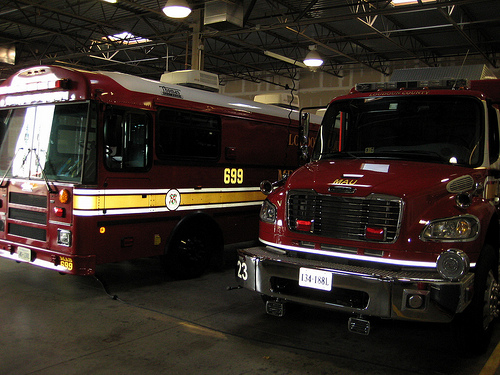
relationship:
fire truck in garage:
[236, 75, 498, 336] [7, 3, 497, 368]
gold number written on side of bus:
[224, 164, 245, 187] [4, 58, 338, 282]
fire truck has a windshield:
[236, 75, 498, 336] [331, 95, 491, 164]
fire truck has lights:
[236, 75, 498, 336] [354, 82, 476, 89]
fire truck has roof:
[236, 75, 498, 336] [337, 91, 498, 95]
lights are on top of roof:
[354, 82, 476, 89] [337, 91, 498, 95]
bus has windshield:
[4, 58, 338, 282] [5, 108, 87, 178]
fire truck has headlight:
[236, 75, 498, 336] [426, 218, 473, 242]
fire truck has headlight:
[236, 75, 498, 336] [253, 200, 278, 225]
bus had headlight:
[4, 58, 338, 282] [59, 232, 73, 248]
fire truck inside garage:
[236, 75, 498, 336] [7, 3, 497, 368]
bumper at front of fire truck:
[236, 261, 472, 326] [236, 75, 498, 336]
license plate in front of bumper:
[298, 267, 335, 292] [236, 261, 472, 326]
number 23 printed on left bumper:
[236, 262, 249, 281] [236, 261, 472, 326]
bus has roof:
[4, 58, 338, 282] [77, 91, 292, 108]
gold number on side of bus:
[224, 164, 245, 187] [4, 58, 338, 282]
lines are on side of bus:
[94, 192, 262, 205] [4, 58, 338, 282]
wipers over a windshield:
[315, 146, 451, 159] [331, 95, 491, 164]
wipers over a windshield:
[1, 149, 58, 194] [5, 108, 87, 178]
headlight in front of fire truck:
[426, 218, 473, 242] [236, 75, 498, 336]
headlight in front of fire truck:
[253, 200, 278, 225] [236, 75, 498, 336]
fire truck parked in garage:
[236, 75, 498, 336] [7, 3, 497, 368]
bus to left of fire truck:
[4, 58, 338, 282] [236, 75, 498, 336]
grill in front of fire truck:
[289, 192, 398, 242] [236, 75, 498, 336]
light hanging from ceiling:
[161, 2, 195, 27] [3, 4, 498, 95]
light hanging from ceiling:
[306, 54, 323, 73] [3, 4, 498, 95]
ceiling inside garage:
[3, 4, 498, 95] [7, 3, 497, 368]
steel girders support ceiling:
[261, 17, 351, 44] [3, 4, 498, 95]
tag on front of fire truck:
[329, 174, 362, 193] [236, 75, 498, 336]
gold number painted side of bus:
[224, 164, 245, 187] [4, 58, 338, 282]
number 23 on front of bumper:
[236, 262, 249, 281] [236, 261, 472, 326]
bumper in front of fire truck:
[236, 261, 472, 326] [236, 75, 498, 336]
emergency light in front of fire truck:
[294, 218, 311, 232] [236, 75, 498, 336]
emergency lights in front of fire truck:
[369, 226, 385, 241] [236, 75, 498, 336]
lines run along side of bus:
[94, 192, 262, 205] [4, 58, 338, 282]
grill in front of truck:
[289, 192, 398, 242] [236, 75, 498, 336]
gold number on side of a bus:
[224, 164, 245, 187] [4, 58, 338, 282]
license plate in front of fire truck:
[298, 267, 335, 292] [236, 75, 498, 336]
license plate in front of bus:
[15, 246, 37, 265] [4, 58, 338, 282]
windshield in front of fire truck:
[331, 95, 491, 164] [236, 75, 498, 336]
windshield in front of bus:
[5, 108, 87, 178] [4, 58, 338, 282]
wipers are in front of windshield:
[1, 149, 58, 194] [5, 108, 87, 178]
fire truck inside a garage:
[236, 75, 498, 336] [7, 3, 497, 368]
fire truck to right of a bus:
[236, 75, 498, 336] [4, 58, 338, 282]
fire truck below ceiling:
[236, 75, 498, 336] [3, 4, 498, 95]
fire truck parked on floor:
[236, 75, 498, 336] [8, 327, 499, 369]